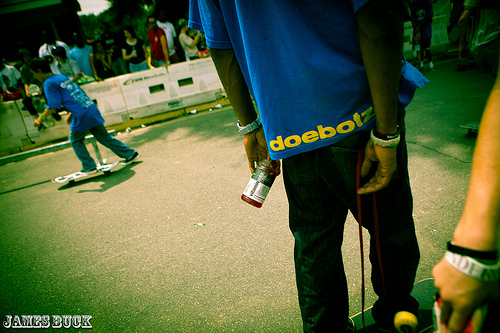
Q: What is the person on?
A: Skateboard.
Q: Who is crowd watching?
A: Skateboarder.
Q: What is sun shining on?
A: Ground.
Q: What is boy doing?
A: Skateboarding.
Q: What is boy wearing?
A: Blue shirt.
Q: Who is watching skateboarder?
A: Spectators.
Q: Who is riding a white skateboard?
A: A man.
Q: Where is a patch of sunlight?
A: On the pavement.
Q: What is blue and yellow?
A: A shirt.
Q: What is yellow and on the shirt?
A: Letters.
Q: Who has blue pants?
A: A boy.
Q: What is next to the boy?
A: Grey concrete.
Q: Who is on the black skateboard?
A: A boy.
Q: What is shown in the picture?
A: A skate park.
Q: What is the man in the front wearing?
A: Jeans.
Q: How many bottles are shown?
A: One.